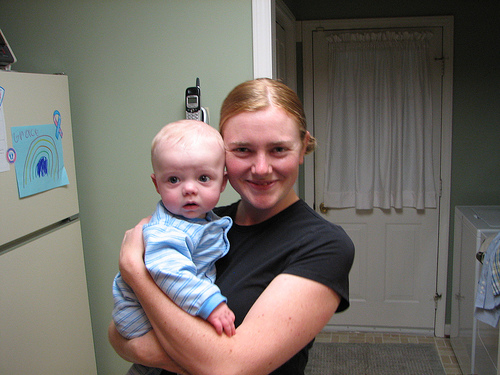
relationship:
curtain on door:
[330, 32, 438, 208] [311, 32, 439, 338]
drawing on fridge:
[9, 127, 71, 197] [1, 70, 96, 374]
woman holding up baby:
[218, 81, 356, 373] [115, 118, 235, 362]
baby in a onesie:
[115, 118, 235, 362] [140, 202, 231, 320]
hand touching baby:
[119, 216, 152, 286] [115, 118, 235, 362]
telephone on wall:
[184, 77, 203, 118] [66, 2, 156, 374]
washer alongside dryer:
[446, 203, 497, 371] [473, 232, 498, 374]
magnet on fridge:
[5, 146, 16, 164] [1, 70, 96, 374]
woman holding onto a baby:
[218, 81, 356, 373] [115, 118, 235, 362]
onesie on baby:
[140, 202, 231, 320] [115, 118, 235, 362]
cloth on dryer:
[473, 234, 499, 329] [473, 232, 498, 374]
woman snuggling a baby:
[218, 81, 356, 373] [115, 118, 235, 362]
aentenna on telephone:
[195, 77, 200, 90] [184, 77, 203, 118]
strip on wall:
[252, 2, 276, 82] [66, 2, 156, 374]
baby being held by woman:
[115, 118, 235, 362] [218, 81, 356, 373]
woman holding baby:
[218, 81, 356, 373] [115, 118, 235, 362]